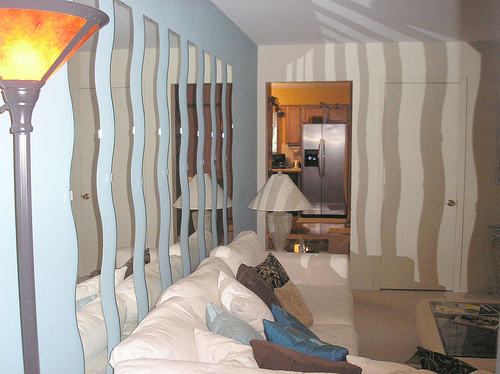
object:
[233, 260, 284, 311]
pillows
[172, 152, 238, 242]
reflection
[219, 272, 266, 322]
throw pillow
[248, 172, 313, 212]
lampshade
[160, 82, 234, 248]
mirror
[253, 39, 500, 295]
wall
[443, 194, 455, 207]
door knob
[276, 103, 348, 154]
cabinets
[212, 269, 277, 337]
pillows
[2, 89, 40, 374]
pole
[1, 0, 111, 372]
floor lamp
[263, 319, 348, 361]
pillow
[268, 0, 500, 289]
stripe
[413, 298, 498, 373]
coffee table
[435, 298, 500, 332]
magazines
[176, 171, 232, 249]
lamp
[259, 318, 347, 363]
pillow part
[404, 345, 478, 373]
pillow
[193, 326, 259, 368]
pillow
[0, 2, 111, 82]
lampshade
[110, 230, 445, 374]
couch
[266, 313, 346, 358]
pillow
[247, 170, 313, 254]
lamp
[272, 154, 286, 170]
coffee maker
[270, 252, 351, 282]
arm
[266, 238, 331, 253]
end table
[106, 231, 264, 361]
back section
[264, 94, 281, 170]
mirror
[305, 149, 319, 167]
ice maker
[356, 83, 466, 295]
door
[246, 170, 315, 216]
shade